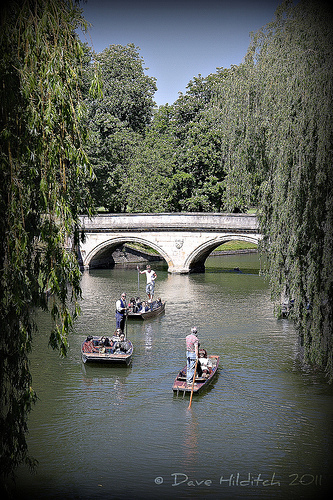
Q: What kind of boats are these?
A: Gondolas.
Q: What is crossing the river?
A: Bridge.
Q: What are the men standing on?
A: Boats.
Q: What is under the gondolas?
A: Water.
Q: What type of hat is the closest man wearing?
A: Cowboy.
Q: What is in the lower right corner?
A: Photographer's name.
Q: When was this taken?
A: 2011.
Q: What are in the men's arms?
A: Oars.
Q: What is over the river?
A: A bridge.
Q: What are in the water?
A: Boats.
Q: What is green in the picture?
A: Trees.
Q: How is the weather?
A: Sunny.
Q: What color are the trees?
A: Green.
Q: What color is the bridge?
A: White.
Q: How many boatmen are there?
A: Three.